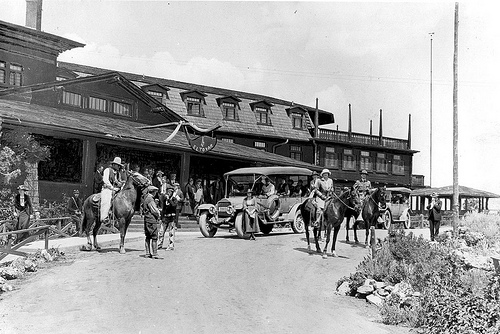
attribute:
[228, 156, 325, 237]
car — antique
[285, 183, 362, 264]
horse — black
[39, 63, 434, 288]
picture — black, white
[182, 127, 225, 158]
plane — wooden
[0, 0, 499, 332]
picture — black and white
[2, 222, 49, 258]
rail — wood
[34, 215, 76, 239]
rail — wood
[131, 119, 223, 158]
sign — old fashioned